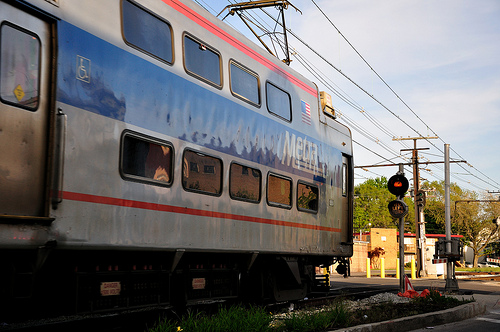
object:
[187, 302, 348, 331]
grass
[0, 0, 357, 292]
train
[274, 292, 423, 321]
rocks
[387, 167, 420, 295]
traffic signal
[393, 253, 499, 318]
concrete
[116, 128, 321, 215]
windows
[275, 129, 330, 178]
logo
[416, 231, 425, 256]
part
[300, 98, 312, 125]
flag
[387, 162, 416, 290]
light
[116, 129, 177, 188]
window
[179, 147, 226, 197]
window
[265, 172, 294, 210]
window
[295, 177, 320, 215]
window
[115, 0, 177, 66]
window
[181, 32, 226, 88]
window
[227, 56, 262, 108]
window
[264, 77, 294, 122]
window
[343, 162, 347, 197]
window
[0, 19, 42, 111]
window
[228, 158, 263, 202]
window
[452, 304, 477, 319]
edge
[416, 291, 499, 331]
road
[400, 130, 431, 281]
post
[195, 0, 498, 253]
power lines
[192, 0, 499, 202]
wires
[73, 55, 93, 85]
sign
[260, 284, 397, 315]
tracks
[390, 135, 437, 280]
poles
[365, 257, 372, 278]
post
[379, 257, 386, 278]
post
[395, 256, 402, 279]
post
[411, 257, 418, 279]
post